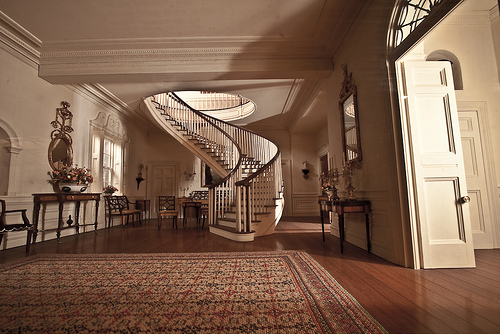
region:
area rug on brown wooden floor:
[0, 215, 497, 330]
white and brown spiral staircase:
[140, 90, 285, 237]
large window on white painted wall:
[0, 20, 145, 245]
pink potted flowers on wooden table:
[25, 160, 100, 245]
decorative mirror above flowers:
[45, 96, 90, 191]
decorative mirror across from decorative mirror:
[45, 65, 361, 170]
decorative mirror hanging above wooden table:
[315, 65, 370, 255]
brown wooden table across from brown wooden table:
[35, 190, 371, 255]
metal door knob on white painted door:
[400, 55, 475, 265]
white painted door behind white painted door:
[401, 60, 492, 266]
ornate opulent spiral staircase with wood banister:
[141, 88, 294, 243]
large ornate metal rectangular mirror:
[333, 57, 370, 172]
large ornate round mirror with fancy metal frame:
[43, 95, 82, 175]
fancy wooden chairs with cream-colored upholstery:
[105, 192, 141, 227]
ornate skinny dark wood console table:
[29, 190, 104, 241]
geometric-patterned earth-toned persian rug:
[10, 252, 388, 330]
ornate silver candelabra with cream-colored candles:
[321, 156, 359, 201]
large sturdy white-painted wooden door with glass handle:
[396, 57, 484, 272]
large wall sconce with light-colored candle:
[296, 157, 313, 184]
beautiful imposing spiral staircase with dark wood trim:
[140, 82, 293, 242]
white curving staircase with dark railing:
[142, 93, 284, 242]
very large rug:
[5, 249, 387, 331]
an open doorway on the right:
[393, 10, 498, 267]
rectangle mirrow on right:
[337, 76, 364, 168]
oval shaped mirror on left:
[49, 133, 74, 169]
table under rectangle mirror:
[319, 195, 370, 253]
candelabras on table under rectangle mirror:
[314, 151, 357, 199]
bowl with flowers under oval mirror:
[46, 165, 93, 191]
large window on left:
[92, 135, 122, 187]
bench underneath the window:
[105, 197, 139, 230]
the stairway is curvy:
[150, 95, 306, 272]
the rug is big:
[10, 248, 320, 332]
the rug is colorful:
[42, 271, 334, 323]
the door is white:
[402, 110, 482, 260]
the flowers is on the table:
[54, 158, 96, 189]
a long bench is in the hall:
[104, 197, 162, 223]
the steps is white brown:
[217, 153, 251, 237]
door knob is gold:
[457, 195, 467, 203]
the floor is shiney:
[342, 249, 462, 327]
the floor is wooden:
[385, 262, 499, 331]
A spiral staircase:
[207, 128, 242, 152]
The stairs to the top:
[219, 220, 234, 232]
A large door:
[417, 89, 452, 199]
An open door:
[421, 100, 454, 218]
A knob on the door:
[462, 195, 469, 202]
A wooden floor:
[416, 280, 474, 295]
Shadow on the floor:
[430, 317, 478, 332]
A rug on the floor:
[108, 271, 235, 329]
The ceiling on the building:
[92, 9, 192, 26]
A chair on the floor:
[159, 196, 175, 213]